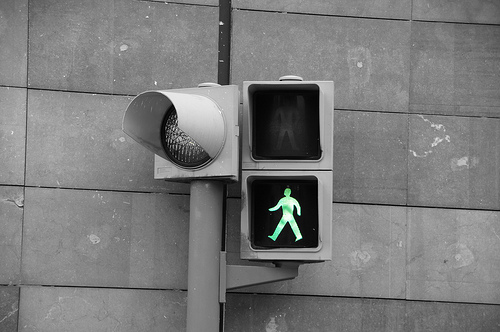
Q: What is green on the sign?
A: Walk sign.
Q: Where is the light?
A: On the pole.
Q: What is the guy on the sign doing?
A: Walking.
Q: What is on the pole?
A: Traffic lights.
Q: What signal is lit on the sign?
A: Walking.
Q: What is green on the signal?
A: Walking symbol.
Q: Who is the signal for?
A: Pedestrians.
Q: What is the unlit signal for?
A: No Walking.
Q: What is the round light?
A: Traffic signal.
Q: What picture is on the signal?
A: Person walking.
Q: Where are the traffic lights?
A: On the pole.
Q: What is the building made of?
A: Cement blocks.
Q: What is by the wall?
A: The traffic light.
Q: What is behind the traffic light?
A: The wall.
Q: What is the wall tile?
A: Rectangular.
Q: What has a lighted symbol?
A: The traffic light.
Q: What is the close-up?
A: The traffic light.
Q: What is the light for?
A: Stop and go.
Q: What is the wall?
A: Cinder blocks.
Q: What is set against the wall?
A: The traffic light.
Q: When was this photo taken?
A: Daytime.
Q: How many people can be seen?
A: 0.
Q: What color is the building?
A: Gray.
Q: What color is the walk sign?
A: Green.